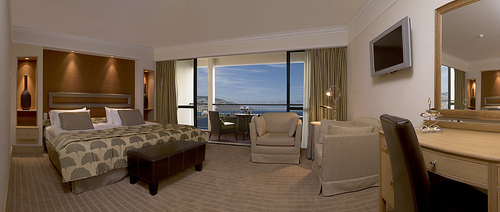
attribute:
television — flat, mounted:
[362, 15, 415, 80]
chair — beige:
[250, 111, 306, 168]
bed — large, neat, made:
[42, 102, 209, 190]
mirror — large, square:
[434, 2, 499, 119]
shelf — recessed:
[18, 110, 38, 126]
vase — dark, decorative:
[21, 73, 33, 110]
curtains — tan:
[155, 61, 177, 123]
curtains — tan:
[308, 50, 348, 119]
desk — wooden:
[379, 115, 499, 211]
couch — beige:
[311, 119, 381, 196]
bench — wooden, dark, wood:
[129, 140, 205, 195]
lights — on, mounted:
[66, 50, 116, 61]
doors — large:
[176, 53, 306, 146]